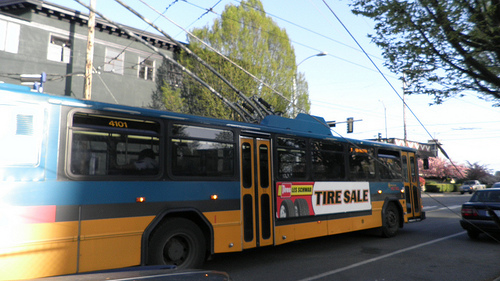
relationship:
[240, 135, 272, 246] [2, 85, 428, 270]
door on bus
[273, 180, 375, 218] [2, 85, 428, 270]
sign on side of bus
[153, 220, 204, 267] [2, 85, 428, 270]
black tire on bus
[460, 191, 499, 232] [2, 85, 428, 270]
car next to bus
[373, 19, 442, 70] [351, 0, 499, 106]
leaves on tree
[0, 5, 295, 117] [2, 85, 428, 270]
building next to bus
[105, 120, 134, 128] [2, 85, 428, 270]
number on side of bus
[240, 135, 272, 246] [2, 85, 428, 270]
doors on bus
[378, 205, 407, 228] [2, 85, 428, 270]
wheel on bus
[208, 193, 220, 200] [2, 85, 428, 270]
light on bus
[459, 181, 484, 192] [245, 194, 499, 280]
parked car on road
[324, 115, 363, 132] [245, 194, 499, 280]
street light on road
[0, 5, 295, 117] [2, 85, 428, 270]
building behind bus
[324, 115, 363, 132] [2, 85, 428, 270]
traffic signal above bus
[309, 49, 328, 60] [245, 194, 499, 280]
light on road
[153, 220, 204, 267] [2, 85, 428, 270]
tire on bus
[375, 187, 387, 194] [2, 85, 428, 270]
light on bus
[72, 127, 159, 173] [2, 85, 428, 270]
window on bus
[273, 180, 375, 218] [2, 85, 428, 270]
advertisement on bus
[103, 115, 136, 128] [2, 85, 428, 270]
orange letters on bus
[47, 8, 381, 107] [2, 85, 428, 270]
wires above bus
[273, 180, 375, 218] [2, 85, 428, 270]
advertisement on side of bus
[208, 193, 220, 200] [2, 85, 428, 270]
light on side of bus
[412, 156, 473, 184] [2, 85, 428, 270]
trees in front of bus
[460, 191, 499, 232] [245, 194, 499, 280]
car parked on road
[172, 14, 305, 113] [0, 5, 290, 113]
tree next to building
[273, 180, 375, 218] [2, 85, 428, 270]
advertising sign on side of bus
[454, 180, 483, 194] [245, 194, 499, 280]
parked car on road